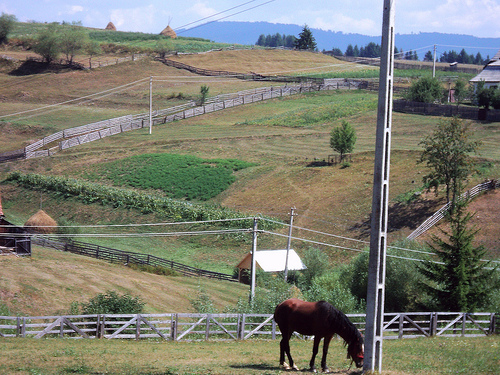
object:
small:
[468, 55, 499, 108]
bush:
[170, 88, 212, 97]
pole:
[366, 0, 396, 372]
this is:
[8, 8, 395, 169]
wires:
[115, 19, 268, 47]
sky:
[233, 1, 286, 18]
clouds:
[409, 6, 495, 29]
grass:
[152, 355, 222, 367]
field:
[0, 0, 500, 375]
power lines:
[160, 17, 268, 39]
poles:
[149, 73, 153, 139]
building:
[466, 58, 500, 119]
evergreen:
[295, 24, 320, 51]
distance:
[451, 53, 499, 106]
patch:
[307, 89, 343, 120]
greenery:
[310, 91, 366, 131]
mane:
[320, 297, 365, 345]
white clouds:
[83, 5, 176, 26]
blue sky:
[284, 6, 357, 24]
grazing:
[336, 335, 371, 372]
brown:
[287, 302, 316, 334]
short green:
[191, 274, 246, 301]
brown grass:
[244, 183, 301, 211]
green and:
[185, 132, 354, 220]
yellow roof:
[471, 59, 499, 91]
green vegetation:
[130, 169, 217, 193]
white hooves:
[288, 360, 298, 366]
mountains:
[187, 20, 499, 61]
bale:
[22, 208, 65, 234]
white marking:
[356, 333, 372, 365]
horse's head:
[347, 328, 367, 367]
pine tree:
[328, 117, 360, 160]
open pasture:
[0, 78, 498, 374]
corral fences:
[21, 78, 406, 160]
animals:
[272, 298, 367, 373]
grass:
[132, 155, 224, 187]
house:
[232, 248, 305, 287]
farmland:
[0, 0, 500, 375]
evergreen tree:
[412, 210, 500, 317]